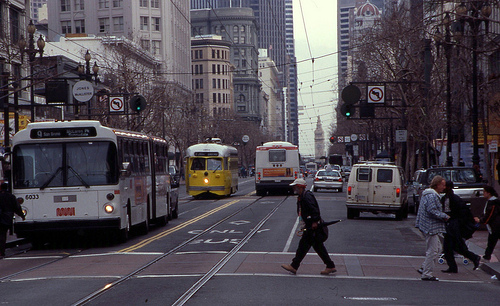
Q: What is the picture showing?
A: It is showing a road.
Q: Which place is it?
A: It is a road.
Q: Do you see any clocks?
A: No, there are no clocks.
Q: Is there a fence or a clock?
A: No, there are no clocks or fences.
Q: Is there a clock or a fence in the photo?
A: No, there are no clocks or fences.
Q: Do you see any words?
A: Yes, there are words.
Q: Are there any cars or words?
A: Yes, there are words.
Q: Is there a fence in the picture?
A: No, there are no fences.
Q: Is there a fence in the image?
A: No, there are no fences.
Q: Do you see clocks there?
A: No, there are no clocks.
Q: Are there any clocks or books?
A: No, there are no clocks or books.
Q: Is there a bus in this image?
A: Yes, there is a bus.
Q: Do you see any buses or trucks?
A: Yes, there is a bus.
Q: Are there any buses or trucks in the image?
A: Yes, there is a bus.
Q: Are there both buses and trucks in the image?
A: No, there is a bus but no trucks.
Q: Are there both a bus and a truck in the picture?
A: No, there is a bus but no trucks.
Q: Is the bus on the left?
A: Yes, the bus is on the left of the image.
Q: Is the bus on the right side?
A: No, the bus is on the left of the image.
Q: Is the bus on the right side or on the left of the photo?
A: The bus is on the left of the image.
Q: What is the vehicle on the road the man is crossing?
A: The vehicle is a bus.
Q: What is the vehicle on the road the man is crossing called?
A: The vehicle is a bus.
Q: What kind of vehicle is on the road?
A: The vehicle is a bus.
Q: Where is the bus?
A: The bus is on the road.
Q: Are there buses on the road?
A: Yes, there is a bus on the road.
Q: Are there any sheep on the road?
A: No, there is a bus on the road.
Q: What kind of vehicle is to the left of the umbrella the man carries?
A: The vehicle is a bus.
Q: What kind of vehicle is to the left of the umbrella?
A: The vehicle is a bus.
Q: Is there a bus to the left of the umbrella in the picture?
A: Yes, there is a bus to the left of the umbrella.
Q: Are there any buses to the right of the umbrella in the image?
A: No, the bus is to the left of the umbrella.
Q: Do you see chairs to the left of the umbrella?
A: No, there is a bus to the left of the umbrella.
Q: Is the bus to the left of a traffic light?
A: No, the bus is to the left of the umbrella.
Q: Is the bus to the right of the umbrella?
A: No, the bus is to the left of the umbrella.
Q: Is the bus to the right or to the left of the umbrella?
A: The bus is to the left of the umbrella.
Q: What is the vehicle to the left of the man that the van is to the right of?
A: The vehicle is a bus.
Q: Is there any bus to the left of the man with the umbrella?
A: Yes, there is a bus to the left of the man.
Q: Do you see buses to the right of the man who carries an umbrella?
A: No, the bus is to the left of the man.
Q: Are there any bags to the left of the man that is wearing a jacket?
A: No, there is a bus to the left of the man.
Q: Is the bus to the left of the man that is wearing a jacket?
A: Yes, the bus is to the left of the man.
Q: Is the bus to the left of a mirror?
A: No, the bus is to the left of the man.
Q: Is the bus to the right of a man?
A: No, the bus is to the left of a man.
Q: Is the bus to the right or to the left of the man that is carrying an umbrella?
A: The bus is to the left of the man.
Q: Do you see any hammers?
A: No, there are no hammers.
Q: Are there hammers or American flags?
A: No, there are no hammers or American flags.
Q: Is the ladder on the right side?
A: Yes, the ladder is on the right of the image.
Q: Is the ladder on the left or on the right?
A: The ladder is on the right of the image.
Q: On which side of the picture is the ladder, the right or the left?
A: The ladder is on the right of the image.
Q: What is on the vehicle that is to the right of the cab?
A: The ladder is on the van.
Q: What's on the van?
A: The ladder is on the van.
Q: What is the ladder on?
A: The ladder is on the van.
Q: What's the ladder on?
A: The ladder is on the van.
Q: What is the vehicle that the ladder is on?
A: The vehicle is a van.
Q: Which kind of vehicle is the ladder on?
A: The ladder is on the van.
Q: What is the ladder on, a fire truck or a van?
A: The ladder is on a van.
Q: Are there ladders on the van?
A: Yes, there is a ladder on the van.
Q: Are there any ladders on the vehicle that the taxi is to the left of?
A: Yes, there is a ladder on the van.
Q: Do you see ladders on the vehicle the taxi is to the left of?
A: Yes, there is a ladder on the van.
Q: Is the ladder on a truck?
A: No, the ladder is on the van.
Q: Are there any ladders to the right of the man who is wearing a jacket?
A: Yes, there is a ladder to the right of the man.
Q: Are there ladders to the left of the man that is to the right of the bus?
A: No, the ladder is to the right of the man.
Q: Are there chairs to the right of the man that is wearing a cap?
A: No, there is a ladder to the right of the man.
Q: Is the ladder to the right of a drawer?
A: No, the ladder is to the right of a man.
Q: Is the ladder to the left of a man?
A: No, the ladder is to the right of a man.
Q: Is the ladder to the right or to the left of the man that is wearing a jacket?
A: The ladder is to the right of the man.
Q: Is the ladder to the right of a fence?
A: No, the ladder is to the right of the taxi cab.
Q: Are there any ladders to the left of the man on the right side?
A: Yes, there is a ladder to the left of the man.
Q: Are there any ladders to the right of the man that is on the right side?
A: No, the ladder is to the left of the man.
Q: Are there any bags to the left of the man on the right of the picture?
A: No, there is a ladder to the left of the man.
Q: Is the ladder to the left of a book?
A: No, the ladder is to the left of the man.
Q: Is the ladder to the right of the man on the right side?
A: No, the ladder is to the left of the man.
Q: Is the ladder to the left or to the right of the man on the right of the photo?
A: The ladder is to the left of the man.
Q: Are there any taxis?
A: Yes, there is a taxi.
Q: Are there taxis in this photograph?
A: Yes, there is a taxi.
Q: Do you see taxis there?
A: Yes, there is a taxi.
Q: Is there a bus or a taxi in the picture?
A: Yes, there is a taxi.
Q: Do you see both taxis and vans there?
A: Yes, there are both a taxi and a van.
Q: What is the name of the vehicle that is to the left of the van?
A: The vehicle is a taxi.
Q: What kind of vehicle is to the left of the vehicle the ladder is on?
A: The vehicle is a taxi.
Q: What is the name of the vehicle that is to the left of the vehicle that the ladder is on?
A: The vehicle is a taxi.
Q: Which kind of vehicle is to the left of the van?
A: The vehicle is a taxi.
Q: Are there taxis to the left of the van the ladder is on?
A: Yes, there is a taxi to the left of the van.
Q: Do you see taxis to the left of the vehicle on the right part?
A: Yes, there is a taxi to the left of the van.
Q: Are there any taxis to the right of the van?
A: No, the taxi is to the left of the van.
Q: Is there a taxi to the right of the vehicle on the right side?
A: No, the taxi is to the left of the van.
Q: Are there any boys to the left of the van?
A: No, there is a taxi to the left of the van.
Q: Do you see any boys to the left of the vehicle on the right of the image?
A: No, there is a taxi to the left of the van.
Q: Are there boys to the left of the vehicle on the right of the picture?
A: No, there is a taxi to the left of the van.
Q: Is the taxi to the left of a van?
A: Yes, the taxi is to the left of a van.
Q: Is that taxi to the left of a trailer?
A: No, the taxi is to the left of a van.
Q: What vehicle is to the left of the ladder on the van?
A: The vehicle is a taxi.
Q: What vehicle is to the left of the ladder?
A: The vehicle is a taxi.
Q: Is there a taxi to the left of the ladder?
A: Yes, there is a taxi to the left of the ladder.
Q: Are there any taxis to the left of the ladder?
A: Yes, there is a taxi to the left of the ladder.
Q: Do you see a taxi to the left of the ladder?
A: Yes, there is a taxi to the left of the ladder.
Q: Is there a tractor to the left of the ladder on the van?
A: No, there is a taxi to the left of the ladder.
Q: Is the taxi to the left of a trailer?
A: No, the taxi is to the left of the ladder.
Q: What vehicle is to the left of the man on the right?
A: The vehicle is a taxi.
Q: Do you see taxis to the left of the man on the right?
A: Yes, there is a taxi to the left of the man.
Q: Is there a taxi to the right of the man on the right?
A: No, the taxi is to the left of the man.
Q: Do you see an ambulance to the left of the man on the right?
A: No, there is a taxi to the left of the man.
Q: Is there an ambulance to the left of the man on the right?
A: No, there is a taxi to the left of the man.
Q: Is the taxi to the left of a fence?
A: No, the taxi is to the left of the man.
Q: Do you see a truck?
A: No, there are no trucks.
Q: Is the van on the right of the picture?
A: Yes, the van is on the right of the image.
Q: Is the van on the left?
A: No, the van is on the right of the image.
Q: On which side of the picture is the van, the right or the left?
A: The van is on the right of the image.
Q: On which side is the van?
A: The van is on the right of the image.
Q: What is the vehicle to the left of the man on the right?
A: The vehicle is a van.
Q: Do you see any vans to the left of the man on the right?
A: Yes, there is a van to the left of the man.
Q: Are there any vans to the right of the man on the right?
A: No, the van is to the left of the man.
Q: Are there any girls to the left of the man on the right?
A: No, there is a van to the left of the man.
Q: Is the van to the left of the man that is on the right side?
A: Yes, the van is to the left of the man.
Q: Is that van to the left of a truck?
A: No, the van is to the left of the man.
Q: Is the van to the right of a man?
A: No, the van is to the left of a man.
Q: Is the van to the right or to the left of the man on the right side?
A: The van is to the left of the man.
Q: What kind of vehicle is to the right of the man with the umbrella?
A: The vehicle is a van.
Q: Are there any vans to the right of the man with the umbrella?
A: Yes, there is a van to the right of the man.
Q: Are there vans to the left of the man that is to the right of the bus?
A: No, the van is to the right of the man.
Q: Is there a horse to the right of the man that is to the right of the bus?
A: No, there is a van to the right of the man.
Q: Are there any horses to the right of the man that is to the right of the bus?
A: No, there is a van to the right of the man.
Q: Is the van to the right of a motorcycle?
A: No, the van is to the right of a man.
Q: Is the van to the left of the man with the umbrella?
A: No, the van is to the right of the man.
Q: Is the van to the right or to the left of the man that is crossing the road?
A: The van is to the right of the man.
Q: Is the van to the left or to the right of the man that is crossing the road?
A: The van is to the right of the man.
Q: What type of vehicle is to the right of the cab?
A: The vehicle is a van.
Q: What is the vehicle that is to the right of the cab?
A: The vehicle is a van.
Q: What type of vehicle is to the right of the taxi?
A: The vehicle is a van.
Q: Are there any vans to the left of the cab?
A: No, the van is to the right of the cab.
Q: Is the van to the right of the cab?
A: Yes, the van is to the right of the cab.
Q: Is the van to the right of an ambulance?
A: No, the van is to the right of the cab.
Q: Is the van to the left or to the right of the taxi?
A: The van is to the right of the taxi.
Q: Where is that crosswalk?
A: The crosswalk is on the road.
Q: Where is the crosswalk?
A: The crosswalk is on the road.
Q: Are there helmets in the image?
A: No, there are no helmets.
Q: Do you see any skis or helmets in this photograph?
A: No, there are no helmets or skis.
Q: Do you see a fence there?
A: No, there are no fences.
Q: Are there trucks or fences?
A: No, there are no fences or trucks.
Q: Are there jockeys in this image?
A: No, there are no jockeys.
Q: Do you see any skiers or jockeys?
A: No, there are no jockeys or skiers.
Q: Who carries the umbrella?
A: The man carries the umbrella.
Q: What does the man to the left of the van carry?
A: The man carries an umbrella.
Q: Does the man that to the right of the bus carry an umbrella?
A: Yes, the man carries an umbrella.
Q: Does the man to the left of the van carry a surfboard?
A: No, the man carries an umbrella.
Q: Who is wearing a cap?
A: The man is wearing a cap.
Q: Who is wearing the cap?
A: The man is wearing a cap.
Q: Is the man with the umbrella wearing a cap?
A: Yes, the man is wearing a cap.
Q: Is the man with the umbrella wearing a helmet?
A: No, the man is wearing a cap.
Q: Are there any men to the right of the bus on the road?
A: Yes, there is a man to the right of the bus.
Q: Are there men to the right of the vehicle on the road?
A: Yes, there is a man to the right of the bus.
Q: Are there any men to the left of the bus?
A: No, the man is to the right of the bus.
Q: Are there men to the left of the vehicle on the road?
A: No, the man is to the right of the bus.